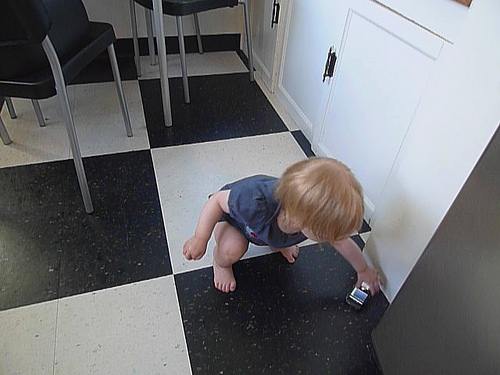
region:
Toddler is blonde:
[168, 153, 385, 310]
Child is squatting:
[174, 151, 388, 317]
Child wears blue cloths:
[175, 145, 400, 327]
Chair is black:
[0, 0, 146, 220]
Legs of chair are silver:
[0, 85, 150, 216]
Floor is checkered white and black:
[10, 37, 215, 367]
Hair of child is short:
[247, 142, 382, 257]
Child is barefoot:
[162, 140, 383, 328]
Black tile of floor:
[0, 145, 180, 312]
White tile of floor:
[0, 76, 156, 173]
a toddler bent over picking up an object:
[180, 153, 390, 313]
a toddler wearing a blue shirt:
[179, 152, 371, 258]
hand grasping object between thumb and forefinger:
[345, 267, 386, 312]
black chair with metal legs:
[2, 3, 133, 212]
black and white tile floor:
[3, 156, 165, 373]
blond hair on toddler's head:
[275, 155, 369, 247]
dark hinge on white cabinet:
[313, 37, 343, 87]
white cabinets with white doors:
[246, 0, 498, 207]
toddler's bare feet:
[213, 242, 304, 288]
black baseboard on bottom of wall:
[125, 27, 248, 59]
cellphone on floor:
[343, 277, 375, 312]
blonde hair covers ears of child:
[275, 151, 367, 248]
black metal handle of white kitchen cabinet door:
[315, 39, 345, 89]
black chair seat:
[51, 20, 116, 50]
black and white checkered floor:
[102, 140, 181, 367]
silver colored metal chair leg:
[106, 53, 140, 140]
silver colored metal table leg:
[148, 0, 179, 130]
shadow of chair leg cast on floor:
[11, 135, 58, 162]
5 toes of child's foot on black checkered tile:
[211, 272, 240, 295]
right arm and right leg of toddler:
[175, 177, 251, 304]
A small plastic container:
[344, 263, 386, 317]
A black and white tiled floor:
[84, 115, 246, 264]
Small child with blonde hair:
[170, 103, 382, 323]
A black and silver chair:
[3, 0, 157, 135]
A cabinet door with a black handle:
[324, 3, 426, 170]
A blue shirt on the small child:
[201, 179, 320, 261]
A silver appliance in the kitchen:
[373, 152, 483, 362]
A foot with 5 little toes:
[202, 256, 251, 306]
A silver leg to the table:
[148, 5, 184, 141]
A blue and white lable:
[343, 282, 373, 317]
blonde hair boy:
[179, 148, 383, 315]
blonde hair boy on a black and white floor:
[180, 154, 382, 315]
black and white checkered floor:
[3, 83, 190, 371]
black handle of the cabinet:
[317, 43, 342, 88]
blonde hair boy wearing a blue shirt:
[181, 153, 380, 297]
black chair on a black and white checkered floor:
[1, 0, 139, 215]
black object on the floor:
[342, 286, 370, 312]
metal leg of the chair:
[45, 38, 100, 215]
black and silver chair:
[1, 3, 146, 222]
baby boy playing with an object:
[179, 154, 386, 309]